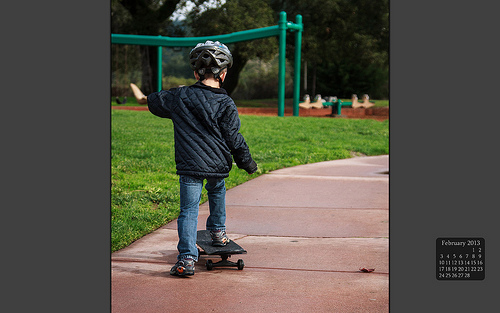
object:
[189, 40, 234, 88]
helmet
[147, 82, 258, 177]
coat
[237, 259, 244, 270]
wheel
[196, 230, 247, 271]
board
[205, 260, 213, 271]
wheel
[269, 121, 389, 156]
grass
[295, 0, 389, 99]
trees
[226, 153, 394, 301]
ground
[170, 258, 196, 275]
shoe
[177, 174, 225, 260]
jeans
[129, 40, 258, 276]
boy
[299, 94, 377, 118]
gras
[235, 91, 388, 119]
playground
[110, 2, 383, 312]
park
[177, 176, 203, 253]
leg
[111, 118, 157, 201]
grass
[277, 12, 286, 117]
pole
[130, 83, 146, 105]
hand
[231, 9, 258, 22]
tree leaves